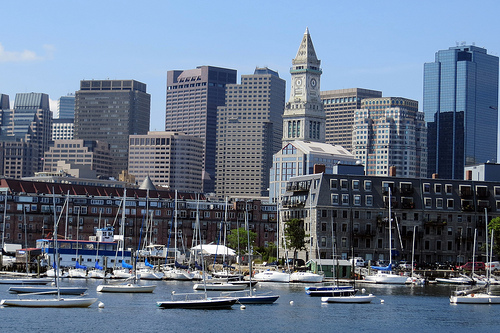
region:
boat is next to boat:
[1, 299, 86, 306]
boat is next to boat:
[10, 288, 86, 296]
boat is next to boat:
[1, 277, 49, 284]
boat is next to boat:
[98, 283, 156, 294]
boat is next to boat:
[157, 298, 234, 308]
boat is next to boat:
[212, 295, 276, 304]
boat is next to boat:
[193, 281, 245, 290]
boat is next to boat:
[217, 281, 259, 286]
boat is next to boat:
[307, 281, 354, 289]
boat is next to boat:
[323, 292, 374, 302]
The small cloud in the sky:
[2, 36, 40, 67]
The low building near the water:
[285, 181, 496, 262]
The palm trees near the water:
[350, 216, 377, 276]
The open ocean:
[21, 313, 498, 325]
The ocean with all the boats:
[7, 281, 498, 309]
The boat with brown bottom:
[154, 286, 239, 316]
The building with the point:
[282, 31, 329, 145]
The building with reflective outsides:
[421, 48, 498, 170]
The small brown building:
[10, 179, 278, 269]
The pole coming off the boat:
[404, 225, 416, 272]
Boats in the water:
[94, 241, 229, 326]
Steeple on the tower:
[292, 25, 336, 82]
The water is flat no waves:
[142, 308, 184, 330]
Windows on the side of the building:
[178, 80, 235, 123]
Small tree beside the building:
[236, 223, 254, 246]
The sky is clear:
[12, 9, 177, 78]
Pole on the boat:
[45, 203, 104, 295]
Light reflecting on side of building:
[428, 63, 479, 148]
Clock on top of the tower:
[285, 68, 320, 87]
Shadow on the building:
[429, 106, 464, 185]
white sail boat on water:
[321, 293, 388, 315]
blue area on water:
[398, 312, 458, 324]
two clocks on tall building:
[289, 63, 327, 95]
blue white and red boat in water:
[31, 234, 138, 269]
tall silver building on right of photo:
[434, 29, 496, 104]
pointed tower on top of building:
[289, 26, 331, 94]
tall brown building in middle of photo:
[161, 55, 231, 119]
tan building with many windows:
[224, 129, 273, 193]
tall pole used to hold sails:
[196, 208, 213, 290]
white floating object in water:
[283, 290, 296, 317]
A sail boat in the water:
[158, 200, 234, 309]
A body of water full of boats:
[1, 276, 499, 330]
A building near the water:
[276, 173, 498, 266]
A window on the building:
[318, 209, 328, 218]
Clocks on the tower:
[295, 75, 319, 87]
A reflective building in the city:
[423, 43, 498, 178]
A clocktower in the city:
[268, 30, 355, 195]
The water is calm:
[2, 276, 499, 331]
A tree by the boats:
[227, 228, 254, 261]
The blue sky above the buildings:
[1, 2, 498, 116]